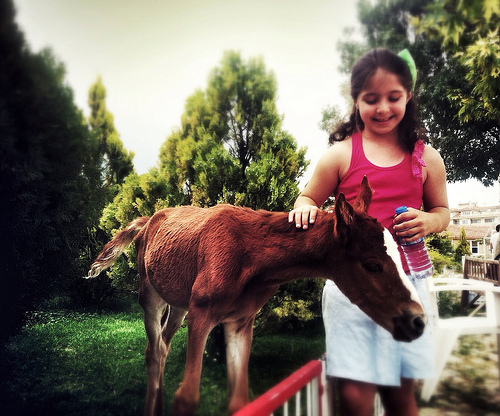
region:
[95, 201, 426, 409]
a young horse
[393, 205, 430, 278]
a plastic water bottle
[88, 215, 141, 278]
the horse has a tail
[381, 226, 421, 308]
white patch on the horse's face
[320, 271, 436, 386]
girl is wearing white shorts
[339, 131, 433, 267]
a pink tank top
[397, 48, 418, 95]
green bow in the girl's hair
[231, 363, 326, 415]
a red and white fence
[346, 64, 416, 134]
the girl is smiling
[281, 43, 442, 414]
the girl is petting the horse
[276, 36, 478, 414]
Girl petting pony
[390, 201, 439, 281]
Clear and blue water bottle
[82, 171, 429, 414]
Brown and white pony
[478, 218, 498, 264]
Person in background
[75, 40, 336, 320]
Green tree behind pony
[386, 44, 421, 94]
Green hairbow in girls hair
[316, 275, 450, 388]
White skirt worn by girl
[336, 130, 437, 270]
Pink tank top worn by girl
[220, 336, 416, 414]
Red and white fence between girl and pony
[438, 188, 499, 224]
White building in the background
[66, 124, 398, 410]
Horse in the yard.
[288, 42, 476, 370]
Girl petting the horse.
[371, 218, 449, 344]
White part on the horse's nose.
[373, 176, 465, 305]
Clear water bottle.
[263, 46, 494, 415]
Girl holding a water bottle.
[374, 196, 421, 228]
Blue cap on the bottle.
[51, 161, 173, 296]
Tail on the mule.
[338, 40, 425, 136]
Bow in the girl's hair.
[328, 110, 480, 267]
Girl with a pink tank.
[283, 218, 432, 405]
Girl with white shorts.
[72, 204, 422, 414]
Small young foal.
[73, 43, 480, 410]
Young girl with a brown foal.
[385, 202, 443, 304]
Plastic water bottle with a blue lid.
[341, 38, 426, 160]
Young girl with brown hair.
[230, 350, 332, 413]
Wooden gate with a red trim.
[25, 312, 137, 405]
Ground covered in green grass.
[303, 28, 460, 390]
Girl wearing a white skirt.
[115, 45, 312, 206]
Green trees covered in leaves.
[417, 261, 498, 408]
white ladder used for climbing on.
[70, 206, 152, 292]
Short brown tail of the foal.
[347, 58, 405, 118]
girl has brown hair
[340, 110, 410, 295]
girl has pink shirt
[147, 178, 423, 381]
small horse near girl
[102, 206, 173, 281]
horse has brown tail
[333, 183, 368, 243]
horse has brown ears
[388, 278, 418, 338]
horse has black nose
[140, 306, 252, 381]
horse has brown legs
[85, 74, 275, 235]
green trees behind horse